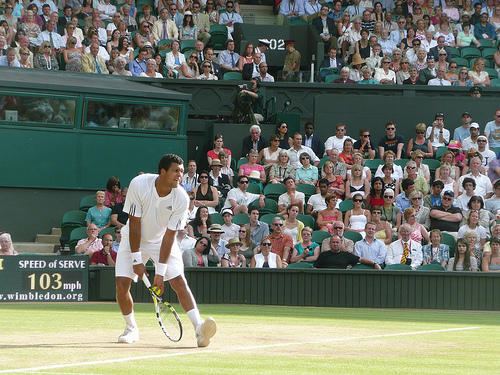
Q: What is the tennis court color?
A: Green.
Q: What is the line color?
A: White.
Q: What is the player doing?
A: Playing tennis.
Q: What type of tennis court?
A: Grass court.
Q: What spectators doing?
A: Watching tennis match.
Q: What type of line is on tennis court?
A: Boundary line.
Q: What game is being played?
A: Tennis.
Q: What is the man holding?
A: Tennis racket.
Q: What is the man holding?
A: Ball.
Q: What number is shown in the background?
A: 103.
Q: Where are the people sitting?
A: In the stands.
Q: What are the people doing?
A: Watching the tennis racket.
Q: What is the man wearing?
A: White shirt.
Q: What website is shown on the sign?
A: Wimbledon.org.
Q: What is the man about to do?
A: Serve the ball.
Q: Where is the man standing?
A: Tennis court.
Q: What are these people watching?
A: A tennis match.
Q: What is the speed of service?
A: 103 mph.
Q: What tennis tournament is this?
A: Wimbledon.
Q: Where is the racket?
A: In his hand.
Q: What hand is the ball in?
A: Left hand.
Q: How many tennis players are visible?
A: One.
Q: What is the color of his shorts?
A: White.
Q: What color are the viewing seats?
A: Green.